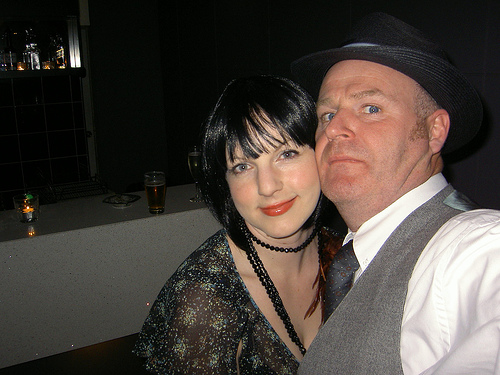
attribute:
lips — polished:
[257, 194, 299, 222]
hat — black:
[287, 4, 494, 164]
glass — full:
[141, 168, 169, 218]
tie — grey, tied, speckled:
[314, 241, 359, 323]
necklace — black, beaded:
[239, 221, 319, 356]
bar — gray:
[1, 182, 224, 367]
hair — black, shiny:
[194, 67, 320, 250]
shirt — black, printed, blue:
[135, 226, 302, 374]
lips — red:
[259, 196, 299, 218]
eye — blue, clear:
[358, 104, 382, 116]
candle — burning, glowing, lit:
[9, 189, 40, 224]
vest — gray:
[295, 186, 476, 373]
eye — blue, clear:
[317, 110, 336, 122]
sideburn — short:
[409, 117, 429, 141]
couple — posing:
[134, 5, 496, 370]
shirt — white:
[342, 170, 498, 374]